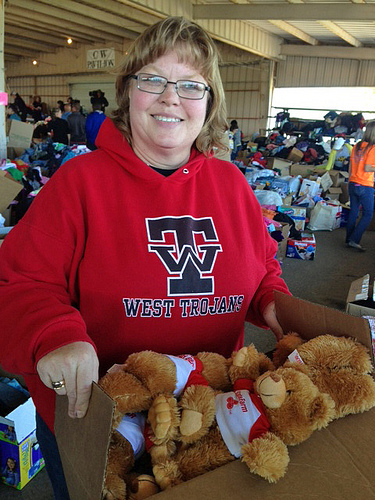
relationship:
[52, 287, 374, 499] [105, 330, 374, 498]
box holding teddy bears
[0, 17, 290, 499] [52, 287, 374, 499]
woman holding box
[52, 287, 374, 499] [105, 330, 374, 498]
box of teddy bears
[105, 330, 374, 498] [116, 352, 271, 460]
teddy bears are wearing shirts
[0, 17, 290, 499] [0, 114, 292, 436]
woman wearing a sweatshirt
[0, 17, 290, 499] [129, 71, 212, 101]
woman wearing glasses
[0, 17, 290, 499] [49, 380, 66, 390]
woman wearing a ring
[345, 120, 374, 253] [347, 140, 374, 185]
girl wearing a shirt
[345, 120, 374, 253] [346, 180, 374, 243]
girl wearing jeans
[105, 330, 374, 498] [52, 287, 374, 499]
teddy bears in a box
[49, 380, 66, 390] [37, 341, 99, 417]
ring on right hand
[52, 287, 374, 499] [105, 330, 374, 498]
box has teddy bears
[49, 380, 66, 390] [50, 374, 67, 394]
ring on finger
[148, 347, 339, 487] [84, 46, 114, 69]
bear wearing a sign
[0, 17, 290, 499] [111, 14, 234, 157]
woman with hair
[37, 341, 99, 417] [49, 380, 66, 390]
hand has a ring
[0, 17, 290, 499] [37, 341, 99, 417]
woman has a hand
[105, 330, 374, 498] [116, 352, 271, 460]
teddy bears wearing shirts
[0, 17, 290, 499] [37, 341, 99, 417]
woman has a right hand